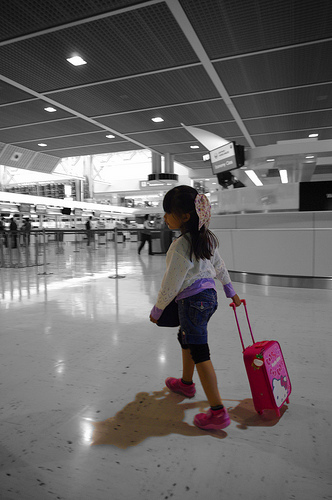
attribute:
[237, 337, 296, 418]
bag — pink, carry on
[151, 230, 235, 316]
shirt — purple, white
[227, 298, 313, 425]
bag — pink, carry on, luggage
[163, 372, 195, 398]
shoe — pink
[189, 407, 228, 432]
shoe — pink